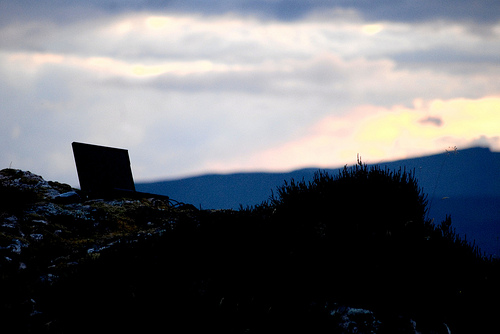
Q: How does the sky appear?
A: Very cloudy.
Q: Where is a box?
A: On hillside.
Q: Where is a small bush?
A: On a hill.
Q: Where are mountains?
A: In far distance.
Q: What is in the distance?
A: Mountain range.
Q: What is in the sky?
A: Clouds.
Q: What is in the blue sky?
A: White clouds.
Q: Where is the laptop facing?
A: The mountain.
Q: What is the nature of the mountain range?
A: Even.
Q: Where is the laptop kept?
A: On a rock.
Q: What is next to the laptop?
A: Grass.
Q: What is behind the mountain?
A: Setting sun.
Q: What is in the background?
A: Mountains.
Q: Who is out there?
A: There isn`t anyone there.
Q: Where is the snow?
A: On the rocks.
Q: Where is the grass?
A: On the montain.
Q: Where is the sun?
A: Behind the clouds.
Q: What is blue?
A: Mountains.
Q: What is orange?
A: Sunset.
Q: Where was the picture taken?
A: Hilltop.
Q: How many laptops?
A: One.